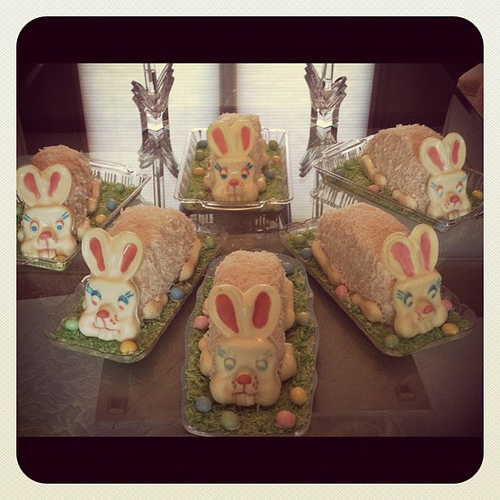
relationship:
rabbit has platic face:
[76, 201, 198, 341] [76, 225, 141, 341]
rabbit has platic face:
[198, 250, 298, 405] [205, 284, 283, 402]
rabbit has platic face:
[309, 202, 450, 341] [381, 220, 447, 336]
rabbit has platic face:
[201, 113, 268, 199] [18, 161, 75, 266]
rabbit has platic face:
[363, 122, 473, 218] [413, 130, 473, 215]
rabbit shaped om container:
[201, 108, 268, 199] [169, 110, 296, 215]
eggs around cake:
[180, 243, 310, 442] [195, 245, 299, 406]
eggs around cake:
[190, 388, 242, 433] [193, 246, 298, 418]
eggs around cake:
[275, 407, 296, 431] [193, 246, 298, 418]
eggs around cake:
[92, 178, 136, 235] [66, 183, 197, 373]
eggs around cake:
[180, 131, 210, 188] [184, 103, 286, 213]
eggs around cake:
[434, 289, 467, 357] [309, 197, 450, 354]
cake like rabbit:
[311, 203, 460, 334] [309, 197, 461, 341]